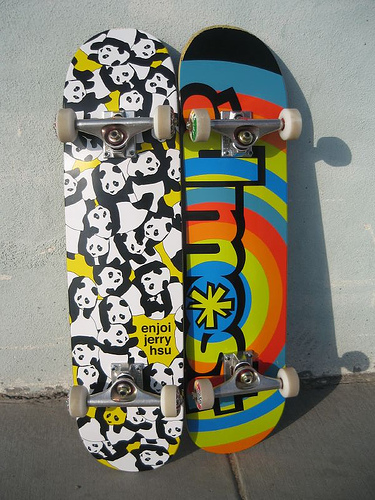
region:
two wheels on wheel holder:
[54, 102, 177, 155]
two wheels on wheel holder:
[66, 364, 180, 415]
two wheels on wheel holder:
[189, 346, 300, 413]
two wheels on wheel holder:
[183, 101, 303, 161]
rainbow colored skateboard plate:
[175, 22, 302, 451]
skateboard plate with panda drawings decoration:
[61, 29, 187, 474]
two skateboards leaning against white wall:
[54, 24, 307, 472]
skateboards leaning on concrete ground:
[3, 390, 373, 474]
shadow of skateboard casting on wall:
[270, 40, 370, 430]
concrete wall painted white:
[1, 1, 57, 383]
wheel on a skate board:
[268, 102, 306, 153]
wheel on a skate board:
[183, 106, 235, 136]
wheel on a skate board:
[270, 360, 315, 390]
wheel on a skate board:
[187, 365, 223, 410]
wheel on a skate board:
[150, 381, 182, 416]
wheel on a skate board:
[63, 384, 97, 418]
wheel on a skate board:
[127, 93, 176, 135]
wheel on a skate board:
[42, 105, 83, 144]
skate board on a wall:
[195, 17, 315, 465]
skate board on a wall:
[58, 19, 179, 480]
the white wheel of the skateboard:
[67, 384, 88, 416]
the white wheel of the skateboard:
[161, 383, 180, 415]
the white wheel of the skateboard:
[192, 377, 213, 411]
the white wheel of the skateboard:
[276, 366, 296, 394]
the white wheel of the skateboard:
[55, 107, 78, 140]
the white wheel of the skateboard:
[153, 105, 176, 138]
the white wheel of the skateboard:
[189, 109, 210, 140]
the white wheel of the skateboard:
[277, 107, 301, 139]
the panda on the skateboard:
[99, 292, 133, 328]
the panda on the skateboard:
[132, 445, 167, 469]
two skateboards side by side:
[56, 19, 305, 475]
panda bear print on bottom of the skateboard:
[61, 29, 190, 460]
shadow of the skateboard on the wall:
[274, 46, 373, 426]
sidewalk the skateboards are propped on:
[6, 399, 374, 499]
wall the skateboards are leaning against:
[2, 5, 365, 371]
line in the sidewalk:
[227, 452, 251, 499]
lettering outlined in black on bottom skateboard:
[180, 81, 264, 414]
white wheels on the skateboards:
[51, 101, 304, 416]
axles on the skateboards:
[56, 100, 283, 415]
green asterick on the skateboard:
[190, 281, 230, 329]